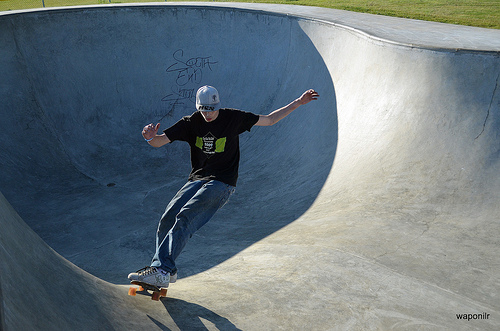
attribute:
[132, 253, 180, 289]
shoes — white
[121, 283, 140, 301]
wheel — orange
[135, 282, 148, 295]
wheel — orange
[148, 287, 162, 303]
wheel — orange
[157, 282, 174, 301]
wheel — orange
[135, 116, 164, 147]
hand — out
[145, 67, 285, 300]
boy — skateboarding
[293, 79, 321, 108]
hand — out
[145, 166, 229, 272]
jeans — blue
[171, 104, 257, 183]
shirt — black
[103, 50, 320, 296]
skateboarder — male, skating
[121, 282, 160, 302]
wheels — orange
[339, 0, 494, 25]
grass — green